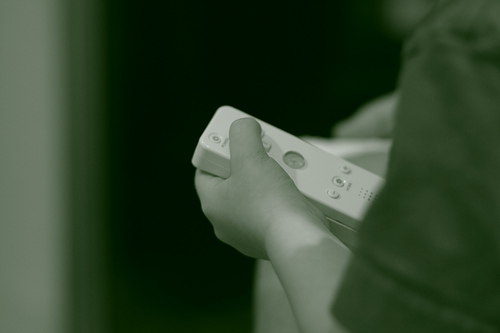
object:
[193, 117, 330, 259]
hand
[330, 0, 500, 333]
person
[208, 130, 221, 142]
button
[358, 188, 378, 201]
holes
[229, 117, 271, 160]
button thumb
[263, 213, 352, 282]
wrist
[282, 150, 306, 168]
button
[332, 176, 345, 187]
button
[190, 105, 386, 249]
controller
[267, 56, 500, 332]
arm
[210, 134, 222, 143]
button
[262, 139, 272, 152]
button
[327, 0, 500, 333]
shirt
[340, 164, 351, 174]
button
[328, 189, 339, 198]
button